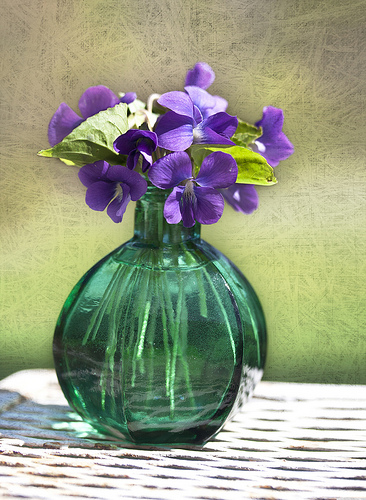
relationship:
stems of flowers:
[60, 201, 264, 421] [42, 56, 297, 230]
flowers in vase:
[42, 56, 297, 230] [42, 182, 275, 453]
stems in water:
[89, 256, 213, 419] [80, 263, 238, 433]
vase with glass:
[54, 183, 267, 447] [53, 184, 266, 446]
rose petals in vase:
[35, 61, 293, 226] [42, 182, 275, 453]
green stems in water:
[76, 189, 261, 427] [48, 235, 268, 450]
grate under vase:
[177, 433, 284, 492] [78, 189, 307, 401]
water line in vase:
[113, 249, 223, 273] [54, 183, 267, 447]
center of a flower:
[173, 173, 203, 196] [145, 150, 238, 226]